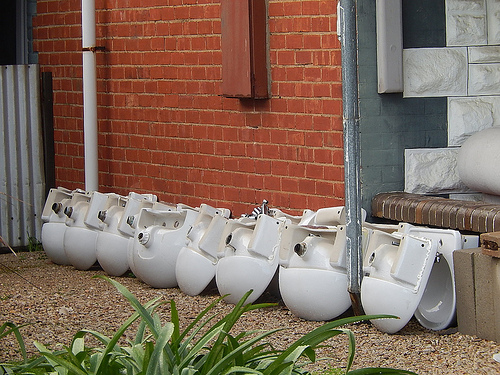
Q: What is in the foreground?
A: Leaves from a plant.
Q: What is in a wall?
A: Bricks.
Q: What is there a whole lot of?
A: Sinks.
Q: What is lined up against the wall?
A: Toilets.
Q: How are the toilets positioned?
A: Facing the wall.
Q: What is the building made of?
A: Red brick.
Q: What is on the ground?
A: Grass.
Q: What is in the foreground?
A: Plants.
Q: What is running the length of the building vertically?
A: White pipe.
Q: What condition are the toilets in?
A: Disrepair.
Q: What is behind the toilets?
A: Metal fence.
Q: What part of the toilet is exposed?
A: Bottom.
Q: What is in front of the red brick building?
A: Grey stone.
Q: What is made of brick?
A: Building.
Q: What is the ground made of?
A: Gravel.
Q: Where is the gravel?
A: The ground.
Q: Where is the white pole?
A: On the building.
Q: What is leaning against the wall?
A: Sinks.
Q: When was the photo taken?
A: Daytime.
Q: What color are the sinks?
A: White.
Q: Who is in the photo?
A: Nobody.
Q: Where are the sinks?
A: Against the wall.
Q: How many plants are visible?
A: One.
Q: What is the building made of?
A: Brick.